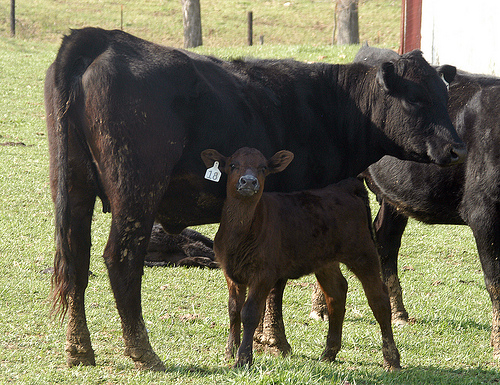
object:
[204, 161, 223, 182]
tag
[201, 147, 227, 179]
ear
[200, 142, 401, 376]
calf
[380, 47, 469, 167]
face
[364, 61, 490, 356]
body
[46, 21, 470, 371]
cow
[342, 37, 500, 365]
cow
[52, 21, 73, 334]
tail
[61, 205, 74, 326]
strands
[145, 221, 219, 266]
animal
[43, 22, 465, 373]
animal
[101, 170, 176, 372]
leg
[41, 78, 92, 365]
leg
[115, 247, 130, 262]
dents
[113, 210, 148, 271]
nicks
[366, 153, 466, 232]
underside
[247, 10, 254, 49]
post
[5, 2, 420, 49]
fence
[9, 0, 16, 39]
post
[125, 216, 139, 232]
knobs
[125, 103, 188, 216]
protrusions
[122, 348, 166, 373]
hoof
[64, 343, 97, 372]
hoof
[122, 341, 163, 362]
mud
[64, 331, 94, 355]
mud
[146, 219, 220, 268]
cow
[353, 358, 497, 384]
shadow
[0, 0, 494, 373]
pasture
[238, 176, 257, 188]
nose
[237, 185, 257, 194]
mouth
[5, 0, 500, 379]
grass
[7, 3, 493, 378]
field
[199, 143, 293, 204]
head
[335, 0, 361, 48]
trunk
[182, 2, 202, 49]
trunk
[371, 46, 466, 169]
head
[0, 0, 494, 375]
view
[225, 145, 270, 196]
face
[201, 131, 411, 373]
cow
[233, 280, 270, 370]
leg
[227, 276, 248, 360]
leg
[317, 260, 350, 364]
leg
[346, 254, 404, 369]
leg